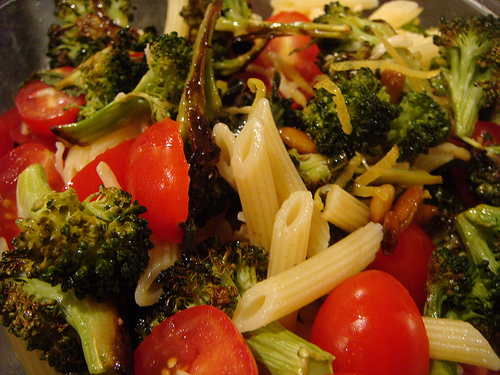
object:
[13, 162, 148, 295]
broccoli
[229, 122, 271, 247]
pasta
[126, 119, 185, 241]
tomato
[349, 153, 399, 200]
cheese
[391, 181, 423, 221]
bean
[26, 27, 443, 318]
salad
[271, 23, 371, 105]
vegetable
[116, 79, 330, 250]
food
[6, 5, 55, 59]
background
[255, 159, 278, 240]
lines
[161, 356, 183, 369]
seeds